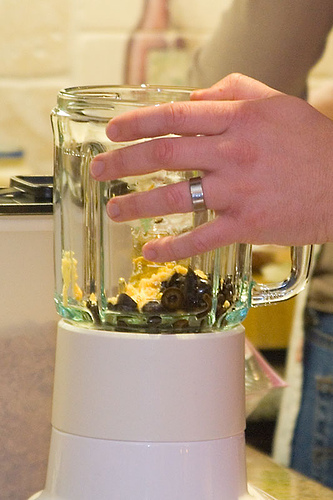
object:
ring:
[187, 175, 208, 214]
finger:
[106, 177, 214, 224]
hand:
[88, 71, 333, 263]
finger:
[141, 212, 230, 263]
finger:
[87, 135, 221, 181]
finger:
[104, 103, 231, 142]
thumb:
[188, 71, 270, 74]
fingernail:
[142, 243, 156, 259]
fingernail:
[106, 200, 120, 219]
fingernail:
[87, 158, 105, 180]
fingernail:
[106, 121, 120, 139]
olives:
[85, 267, 238, 333]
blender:
[50, 86, 314, 333]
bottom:
[43, 319, 249, 500]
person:
[89, 0, 333, 491]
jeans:
[288, 303, 333, 489]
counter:
[243, 436, 283, 499]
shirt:
[172, 1, 332, 311]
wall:
[1, 3, 333, 87]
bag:
[245, 335, 289, 422]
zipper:
[246, 337, 290, 392]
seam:
[50, 427, 248, 440]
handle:
[251, 244, 315, 308]